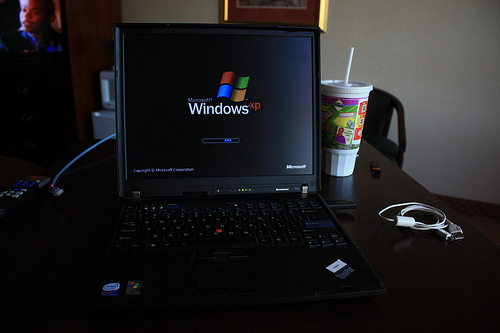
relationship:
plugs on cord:
[445, 233, 461, 241] [381, 205, 462, 243]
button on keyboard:
[215, 229, 222, 234] [122, 204, 349, 255]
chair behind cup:
[363, 93, 408, 168] [326, 44, 367, 178]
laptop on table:
[84, 26, 386, 302] [3, 139, 499, 330]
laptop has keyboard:
[84, 26, 386, 302] [122, 204, 349, 255]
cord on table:
[381, 205, 462, 243] [3, 139, 499, 330]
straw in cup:
[341, 47, 356, 80] [326, 44, 367, 178]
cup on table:
[326, 44, 367, 178] [3, 139, 499, 330]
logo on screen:
[187, 70, 259, 117] [130, 35, 311, 178]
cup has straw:
[326, 44, 367, 178] [341, 47, 356, 80]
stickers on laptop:
[100, 279, 143, 296] [84, 26, 386, 302]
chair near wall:
[363, 93, 408, 168] [335, 1, 493, 200]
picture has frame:
[240, 2, 306, 7] [223, 4, 329, 33]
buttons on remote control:
[12, 178, 35, 189] [4, 169, 51, 212]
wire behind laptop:
[50, 126, 115, 183] [84, 26, 386, 302]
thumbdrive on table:
[370, 161, 381, 179] [3, 139, 499, 330]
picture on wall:
[240, 2, 306, 7] [335, 1, 493, 200]